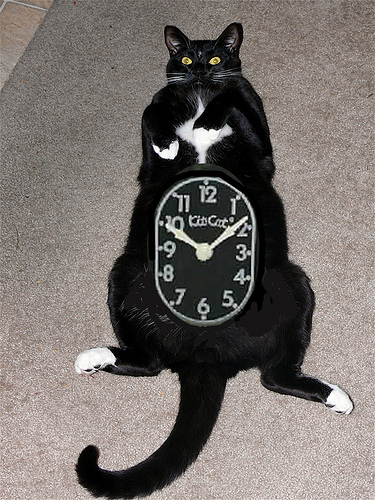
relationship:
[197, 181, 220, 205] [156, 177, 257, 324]
number on clock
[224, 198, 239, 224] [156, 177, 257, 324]
number on clock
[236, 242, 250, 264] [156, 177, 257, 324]
number on clock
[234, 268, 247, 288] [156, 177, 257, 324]
number on clock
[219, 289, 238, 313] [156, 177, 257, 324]
number on clock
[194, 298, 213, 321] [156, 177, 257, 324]
number on clock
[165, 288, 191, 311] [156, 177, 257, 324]
number on clock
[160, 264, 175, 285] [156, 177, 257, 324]
number on clock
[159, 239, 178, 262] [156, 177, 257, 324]
number on clock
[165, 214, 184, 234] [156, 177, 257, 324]
number on clock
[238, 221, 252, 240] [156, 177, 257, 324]
number on clock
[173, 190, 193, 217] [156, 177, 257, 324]
number on clock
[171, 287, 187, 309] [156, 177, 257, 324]
number on clock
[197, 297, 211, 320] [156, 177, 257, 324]
6 on clock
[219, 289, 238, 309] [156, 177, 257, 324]
5 on clock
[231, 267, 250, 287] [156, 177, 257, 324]
4 on clock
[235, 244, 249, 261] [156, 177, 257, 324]
3 on clock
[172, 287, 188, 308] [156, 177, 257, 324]
7 on clock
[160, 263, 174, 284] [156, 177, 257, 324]
8 on clock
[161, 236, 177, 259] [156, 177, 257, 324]
9 on clock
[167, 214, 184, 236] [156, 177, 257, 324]
10 on clock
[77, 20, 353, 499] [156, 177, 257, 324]
cat and clock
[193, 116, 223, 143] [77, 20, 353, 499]
paw of cat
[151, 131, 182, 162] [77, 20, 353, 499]
paw of cat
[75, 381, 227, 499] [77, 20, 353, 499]
tail of cat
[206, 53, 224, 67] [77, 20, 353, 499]
eye of cat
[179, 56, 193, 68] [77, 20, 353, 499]
eye of cat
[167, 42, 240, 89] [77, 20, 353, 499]
face of cat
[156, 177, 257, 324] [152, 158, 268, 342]
clock on stomach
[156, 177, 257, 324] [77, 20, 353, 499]
clock on cat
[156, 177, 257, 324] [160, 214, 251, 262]
clock tells time